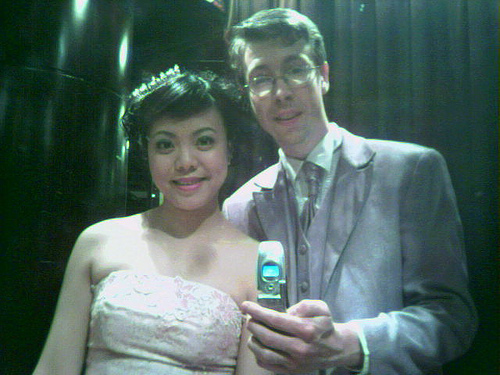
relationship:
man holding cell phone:
[221, 7, 479, 375] [248, 237, 293, 317]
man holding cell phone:
[221, 7, 479, 375] [243, 231, 304, 360]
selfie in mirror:
[41, 20, 472, 368] [1, 0, 496, 372]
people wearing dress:
[31, 63, 277, 375] [52, 256, 293, 373]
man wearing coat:
[174, 20, 456, 341] [230, 131, 477, 307]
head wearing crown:
[94, 62, 271, 230] [100, 45, 193, 112]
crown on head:
[100, 45, 193, 112] [94, 62, 271, 230]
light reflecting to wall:
[115, 22, 129, 82] [5, 7, 128, 210]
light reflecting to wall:
[67, 2, 88, 37] [5, 7, 128, 210]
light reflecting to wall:
[113, 101, 133, 162] [5, 7, 128, 210]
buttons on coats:
[291, 230, 315, 297] [221, 20, 484, 365]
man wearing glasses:
[221, 7, 479, 375] [233, 58, 345, 106]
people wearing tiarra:
[31, 63, 277, 375] [124, 57, 204, 127]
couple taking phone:
[20, 5, 495, 373] [246, 234, 298, 321]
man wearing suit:
[221, 7, 479, 375] [229, 135, 477, 374]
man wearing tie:
[221, 7, 479, 375] [298, 159, 315, 234]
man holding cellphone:
[221, 7, 479, 375] [251, 238, 293, 321]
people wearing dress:
[31, 63, 277, 375] [72, 264, 206, 362]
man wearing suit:
[221, 7, 479, 375] [238, 125, 484, 363]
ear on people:
[314, 52, 336, 96] [31, 63, 277, 375]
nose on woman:
[169, 145, 201, 170] [46, 40, 303, 373]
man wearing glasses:
[221, 7, 479, 375] [243, 60, 320, 92]